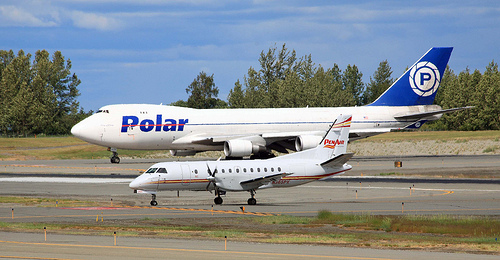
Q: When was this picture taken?
A: Daytime.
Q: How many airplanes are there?
A: 2.